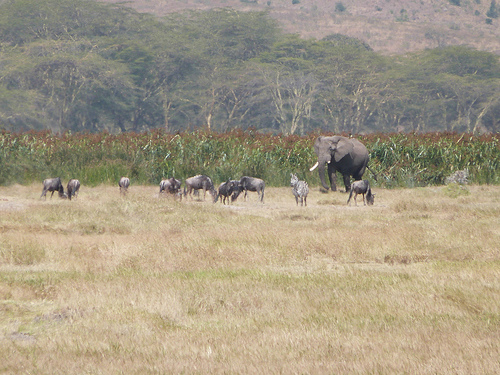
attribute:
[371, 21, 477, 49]
plains — brown, green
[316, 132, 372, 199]
elephant — large, grey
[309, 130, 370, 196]
elephant — big, grey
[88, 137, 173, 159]
corn — growing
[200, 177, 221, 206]
head — down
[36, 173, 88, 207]
animals — facing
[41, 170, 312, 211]
wildabeasts — grazing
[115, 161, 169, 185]
animal — rear end 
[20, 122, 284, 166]
grass — green, brown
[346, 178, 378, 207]
zebra — grazing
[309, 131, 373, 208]
elephant — large, standing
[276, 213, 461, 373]
grass — dry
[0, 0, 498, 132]
trees — bunch 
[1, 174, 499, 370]
grass — brown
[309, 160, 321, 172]
tusks — ivory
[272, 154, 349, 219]
zebra — black, white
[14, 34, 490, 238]
trees — Large ,  distance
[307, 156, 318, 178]
tusk — broken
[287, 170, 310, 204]
zebra — running